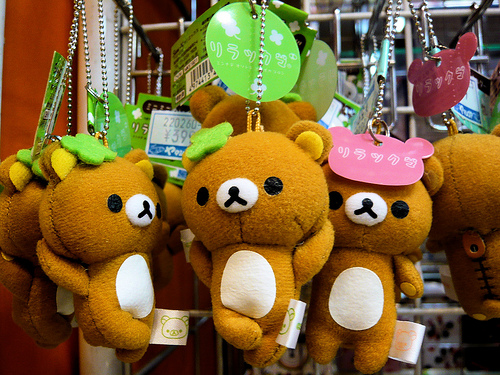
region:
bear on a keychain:
[178, 1, 336, 362]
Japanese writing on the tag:
[328, 137, 417, 177]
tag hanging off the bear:
[132, 305, 193, 348]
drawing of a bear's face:
[390, 318, 420, 358]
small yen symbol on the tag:
[163, 125, 173, 142]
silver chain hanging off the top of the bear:
[71, 4, 116, 161]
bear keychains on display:
[1, 1, 494, 373]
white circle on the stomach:
[322, 261, 393, 338]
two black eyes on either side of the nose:
[322, 185, 419, 230]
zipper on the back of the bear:
[453, 230, 488, 258]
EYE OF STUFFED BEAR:
[259, 171, 288, 199]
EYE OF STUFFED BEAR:
[192, 180, 213, 210]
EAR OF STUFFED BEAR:
[288, 117, 323, 160]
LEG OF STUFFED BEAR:
[211, 305, 265, 350]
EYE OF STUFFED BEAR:
[99, 190, 127, 215]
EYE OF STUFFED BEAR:
[104, 193, 122, 220]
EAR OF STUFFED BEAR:
[35, 136, 76, 179]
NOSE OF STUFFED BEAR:
[352, 193, 382, 210]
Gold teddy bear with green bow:
[177, 112, 337, 355]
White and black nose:
[213, 177, 260, 220]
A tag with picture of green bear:
[148, 298, 198, 353]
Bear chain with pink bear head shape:
[332, 117, 434, 194]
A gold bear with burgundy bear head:
[407, 27, 492, 112]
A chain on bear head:
[72, 4, 134, 86]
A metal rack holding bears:
[77, 2, 184, 86]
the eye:
[262, 172, 285, 198]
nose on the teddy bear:
[349, 199, 382, 221]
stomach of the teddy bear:
[221, 260, 269, 310]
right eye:
[105, 195, 127, 216]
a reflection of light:
[214, 11, 234, 21]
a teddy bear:
[176, 149, 335, 371]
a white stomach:
[121, 264, 154, 311]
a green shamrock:
[66, 133, 114, 160]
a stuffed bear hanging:
[178, 125, 335, 365]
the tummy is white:
[218, 250, 273, 319]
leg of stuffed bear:
[212, 308, 260, 349]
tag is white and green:
[150, 308, 186, 344]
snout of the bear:
[216, 178, 258, 209]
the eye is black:
[263, 175, 280, 195]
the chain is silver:
[250, 0, 268, 117]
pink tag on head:
[326, 126, 430, 186]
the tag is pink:
[407, 30, 478, 116]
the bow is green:
[60, 132, 116, 164]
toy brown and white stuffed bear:
[20, 136, 180, 360]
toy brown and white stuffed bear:
[174, 122, 341, 359]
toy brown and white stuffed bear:
[337, 149, 425, 363]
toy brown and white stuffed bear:
[424, 123, 496, 235]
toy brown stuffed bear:
[15, 141, 185, 366]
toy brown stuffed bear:
[184, 118, 332, 352]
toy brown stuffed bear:
[337, 171, 439, 373]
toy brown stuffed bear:
[432, 126, 497, 261]